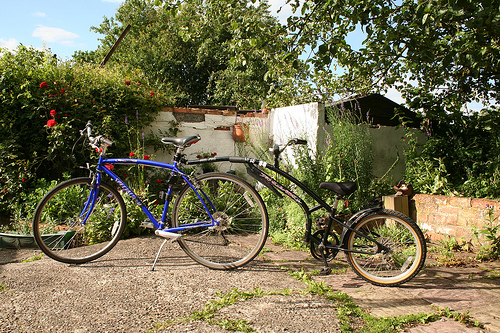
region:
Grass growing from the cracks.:
[203, 280, 346, 327]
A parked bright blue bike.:
[32, 105, 267, 274]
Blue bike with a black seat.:
[153, 128, 208, 153]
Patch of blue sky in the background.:
[62, 5, 102, 28]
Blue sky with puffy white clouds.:
[25, 15, 87, 50]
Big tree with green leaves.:
[92, 5, 283, 88]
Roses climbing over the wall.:
[20, 68, 143, 140]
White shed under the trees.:
[274, 95, 431, 168]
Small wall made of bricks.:
[415, 200, 495, 229]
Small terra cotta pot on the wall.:
[226, 118, 253, 147]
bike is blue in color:
[51, 138, 246, 264]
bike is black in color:
[180, 143, 421, 284]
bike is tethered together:
[40, 132, 425, 282]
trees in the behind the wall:
[90, 15, 331, 85]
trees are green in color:
[157, 10, 269, 85]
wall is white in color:
[270, 102, 320, 151]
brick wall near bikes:
[422, 195, 492, 237]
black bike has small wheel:
[342, 207, 425, 287]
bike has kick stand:
[151, 235, 169, 275]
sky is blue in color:
[21, 6, 91, 38]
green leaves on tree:
[310, 2, 497, 129]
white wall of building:
[138, 101, 426, 180]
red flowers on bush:
[38, 76, 158, 171]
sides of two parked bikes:
[32, 116, 427, 287]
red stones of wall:
[411, 195, 499, 245]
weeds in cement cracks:
[188, 243, 483, 331]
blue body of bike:
[82, 155, 209, 232]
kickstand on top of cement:
[146, 238, 171, 272]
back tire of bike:
[346, 211, 427, 287]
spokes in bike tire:
[44, 184, 115, 254]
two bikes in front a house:
[25, 88, 431, 296]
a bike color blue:
[31, 114, 273, 273]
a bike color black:
[226, 131, 426, 293]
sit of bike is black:
[155, 130, 205, 147]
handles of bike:
[78, 116, 108, 158]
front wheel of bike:
[28, 172, 129, 266]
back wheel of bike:
[173, 169, 272, 273]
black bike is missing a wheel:
[239, 138, 439, 295]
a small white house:
[126, 73, 446, 213]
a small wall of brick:
[397, 176, 499, 269]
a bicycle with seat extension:
[52, 92, 457, 310]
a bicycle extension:
[185, 132, 437, 287]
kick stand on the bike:
[133, 220, 188, 271]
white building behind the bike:
[40, 70, 440, 221]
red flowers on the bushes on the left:
[13, 62, 173, 192]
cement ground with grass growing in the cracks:
[12, 195, 483, 323]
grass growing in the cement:
[212, 257, 489, 328]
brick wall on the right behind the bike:
[365, 162, 496, 270]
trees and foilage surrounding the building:
[2, 51, 479, 234]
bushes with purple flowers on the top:
[306, 88, 382, 184]